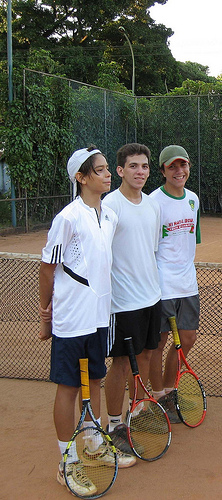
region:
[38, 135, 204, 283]
Three young men standing together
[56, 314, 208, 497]
Three tennis raquets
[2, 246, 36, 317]
Top of the tennis net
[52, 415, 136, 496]
Athletic shoes and socks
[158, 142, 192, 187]
Boy with a green hat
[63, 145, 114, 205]
Boy with a white hat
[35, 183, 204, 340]
Three white shirts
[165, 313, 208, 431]
Red raquet with yellow handle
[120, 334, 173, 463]
Tennis raquet with black handle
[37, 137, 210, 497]
Three tennis players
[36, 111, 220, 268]
3 young friends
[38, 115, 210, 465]
3 juvenile male tennis players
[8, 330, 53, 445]
a clay tennis court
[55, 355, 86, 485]
a tennis racket with a yellow handle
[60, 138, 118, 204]
a boy in a backwards white cap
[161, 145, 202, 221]
a boy in a green baseball hat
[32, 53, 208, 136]
forest behind a fence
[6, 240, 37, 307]
a tennis net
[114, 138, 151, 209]
a boy with short brown hair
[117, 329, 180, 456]
a tennis racket with a black grip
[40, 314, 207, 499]
Three tennis rackets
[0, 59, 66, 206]
Ivy on a fence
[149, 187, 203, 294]
White short-sleeve shirt with green and red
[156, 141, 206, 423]
Smiling young male tennis player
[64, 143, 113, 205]
Boy with a backwards facing cap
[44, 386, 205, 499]
Tennis shoes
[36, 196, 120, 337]
Black and white short sleeve shirt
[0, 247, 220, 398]
Mesh net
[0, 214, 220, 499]
Tennis court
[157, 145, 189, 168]
a green cap on boys head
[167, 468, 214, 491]
a sandy tennis court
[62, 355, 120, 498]
a yellow and blue tennis racket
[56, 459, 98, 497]
a white gym shoe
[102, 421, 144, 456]
a black gym shoe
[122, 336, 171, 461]
a black and red tennis racket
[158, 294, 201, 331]
a pair of grey shorts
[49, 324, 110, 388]
a pair of blue shorts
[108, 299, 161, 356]
a pair of black shorts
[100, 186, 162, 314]
a white tee shirt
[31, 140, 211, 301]
Three smiling boys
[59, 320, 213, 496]
Three tennis rackets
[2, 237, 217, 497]
A dirt tennis court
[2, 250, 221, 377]
A tennis net on a court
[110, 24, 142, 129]
A light pole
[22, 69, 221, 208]
A tall metal fence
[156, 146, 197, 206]
A green with orange trim baseball cap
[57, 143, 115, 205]
A white baseball cap turned backwards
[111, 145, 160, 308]
A boy in a solid white tshirt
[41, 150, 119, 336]
A white shirt with black stripes on the sleeve